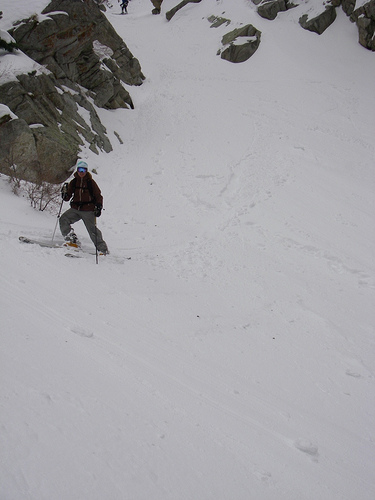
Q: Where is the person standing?
A: On the snow.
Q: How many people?
A: One person.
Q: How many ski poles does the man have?
A: Two.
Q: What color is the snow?
A: White.